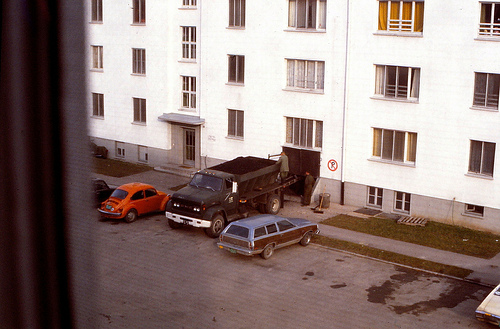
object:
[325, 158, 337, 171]
sign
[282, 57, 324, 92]
window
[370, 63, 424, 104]
window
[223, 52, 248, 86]
window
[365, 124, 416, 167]
window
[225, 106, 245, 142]
window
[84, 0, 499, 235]
building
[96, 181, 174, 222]
car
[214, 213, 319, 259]
car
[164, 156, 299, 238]
truck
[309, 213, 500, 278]
grass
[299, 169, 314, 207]
man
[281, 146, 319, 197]
entrance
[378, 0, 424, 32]
curtains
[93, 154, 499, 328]
floor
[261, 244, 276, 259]
wheel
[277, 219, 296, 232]
window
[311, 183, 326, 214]
broom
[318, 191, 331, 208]
barrel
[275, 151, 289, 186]
man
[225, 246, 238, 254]
license plate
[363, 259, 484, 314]
mark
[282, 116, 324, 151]
window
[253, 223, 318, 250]
brown  panels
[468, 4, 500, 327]
right